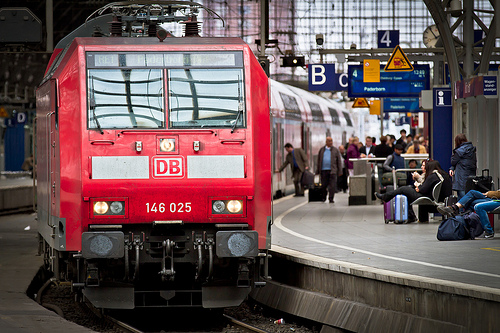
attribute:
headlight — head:
[208, 193, 248, 218]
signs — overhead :
[382, 47, 410, 70]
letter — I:
[429, 87, 449, 107]